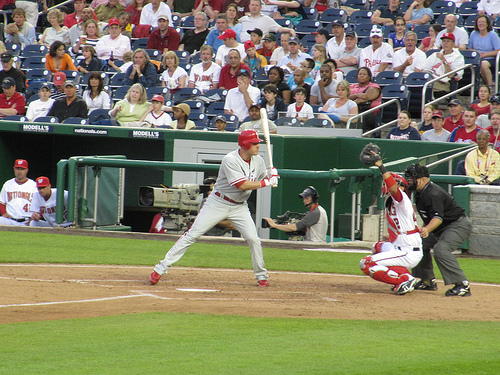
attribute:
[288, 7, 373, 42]
seats — empty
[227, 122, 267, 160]
helmet — red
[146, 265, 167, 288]
shoe — red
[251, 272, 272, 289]
shoe — red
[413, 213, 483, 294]
pants — gray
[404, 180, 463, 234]
shirt — black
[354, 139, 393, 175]
glove — black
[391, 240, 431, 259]
belt — black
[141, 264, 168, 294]
sneaker — red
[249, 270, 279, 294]
sneaker — red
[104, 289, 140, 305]
line — white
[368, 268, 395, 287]
pads — red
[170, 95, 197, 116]
hat — brown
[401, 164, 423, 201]
mask — black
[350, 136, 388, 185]
baseball glove — black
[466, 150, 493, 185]
shirt — yellow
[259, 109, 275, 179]
bat — white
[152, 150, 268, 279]
uniform — white, red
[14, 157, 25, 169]
cap — red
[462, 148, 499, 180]
shirt — yellow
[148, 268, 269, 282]
shoes — red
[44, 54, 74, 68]
shirt — orange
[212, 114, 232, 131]
boy — young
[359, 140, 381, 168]
glove — catchers